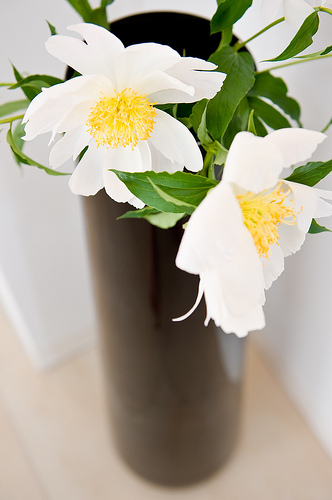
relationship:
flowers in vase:
[35, 33, 323, 343] [60, 171, 247, 498]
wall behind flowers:
[2, 3, 325, 441] [35, 33, 323, 343]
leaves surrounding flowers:
[201, 18, 305, 139] [35, 33, 323, 343]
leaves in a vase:
[201, 18, 305, 139] [60, 171, 247, 498]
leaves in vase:
[201, 18, 305, 139] [60, 171, 247, 498]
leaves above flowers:
[201, 18, 305, 139] [35, 33, 323, 343]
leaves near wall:
[201, 18, 305, 139] [2, 3, 325, 441]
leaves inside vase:
[201, 18, 305, 139] [60, 171, 247, 498]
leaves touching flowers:
[201, 18, 305, 139] [35, 33, 323, 343]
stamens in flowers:
[81, 86, 166, 149] [35, 33, 323, 343]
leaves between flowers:
[201, 18, 305, 139] [35, 33, 323, 343]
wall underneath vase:
[2, 3, 325, 441] [60, 171, 247, 498]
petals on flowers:
[32, 20, 315, 300] [35, 33, 323, 343]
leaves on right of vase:
[201, 18, 305, 139] [60, 171, 247, 498]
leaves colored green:
[201, 18, 305, 139] [221, 63, 254, 88]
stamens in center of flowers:
[81, 86, 166, 149] [35, 33, 323, 343]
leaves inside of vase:
[201, 18, 305, 139] [60, 171, 247, 498]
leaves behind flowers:
[201, 18, 305, 139] [35, 33, 323, 343]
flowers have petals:
[35, 33, 323, 343] [32, 20, 315, 300]